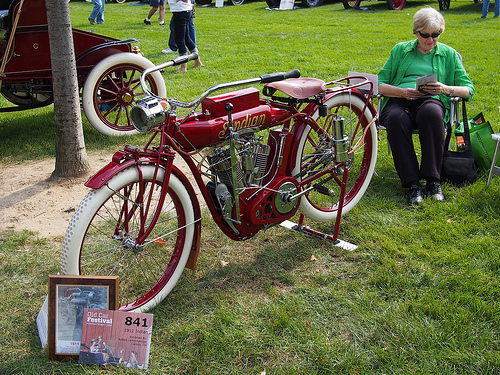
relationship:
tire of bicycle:
[60, 164, 195, 311] [116, 42, 364, 270]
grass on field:
[226, 16, 363, 61] [13, 7, 465, 349]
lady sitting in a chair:
[373, 4, 474, 207] [375, 79, 462, 188]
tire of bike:
[60, 164, 195, 311] [60, 51, 381, 320]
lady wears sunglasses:
[373, 4, 474, 207] [412, 30, 442, 41]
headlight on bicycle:
[128, 95, 165, 133] [65, 46, 386, 308]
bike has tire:
[106, 73, 389, 232] [66, 184, 190, 268]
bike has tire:
[106, 73, 389, 232] [308, 100, 379, 201]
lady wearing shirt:
[373, 4, 474, 207] [375, 39, 474, 121]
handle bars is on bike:
[139, 50, 301, 105] [60, 51, 381, 320]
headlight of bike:
[128, 94, 165, 132] [60, 51, 381, 320]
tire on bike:
[60, 165, 194, 314] [25, 54, 411, 332]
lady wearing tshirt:
[373, 16, 467, 206] [396, 56, 463, 106]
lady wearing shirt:
[373, 16, 467, 206] [363, 30, 478, 106]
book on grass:
[81, 309, 153, 369] [2, 0, 499, 373]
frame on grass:
[46, 274, 118, 361] [2, 0, 499, 373]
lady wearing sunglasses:
[373, 4, 474, 207] [414, 25, 444, 41]